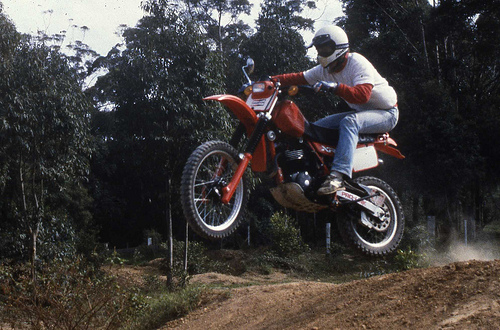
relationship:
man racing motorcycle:
[269, 20, 401, 194] [178, 54, 409, 259]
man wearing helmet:
[269, 20, 401, 194] [311, 24, 353, 70]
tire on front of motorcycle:
[178, 140, 248, 241] [265, 22, 398, 193]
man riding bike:
[269, 20, 401, 194] [186, 24, 420, 260]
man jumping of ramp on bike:
[269, 25, 400, 195] [179, 58, 407, 257]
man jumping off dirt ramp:
[269, 25, 400, 195] [156, 258, 500, 329]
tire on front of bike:
[177, 138, 251, 242] [179, 58, 407, 257]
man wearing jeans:
[269, 20, 401, 194] [295, 104, 461, 216]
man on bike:
[269, 25, 400, 195] [179, 55, 409, 260]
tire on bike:
[178, 140, 248, 241] [179, 55, 409, 260]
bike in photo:
[176, 92, 408, 247] [5, 5, 496, 327]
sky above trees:
[64, 5, 115, 48] [6, 2, 245, 291]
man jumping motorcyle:
[269, 20, 401, 194] [177, 58, 403, 262]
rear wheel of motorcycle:
[337, 174, 407, 261] [182, 73, 413, 252]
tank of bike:
[274, 103, 311, 139] [179, 58, 407, 257]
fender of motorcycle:
[245, 137, 272, 174] [182, 73, 413, 252]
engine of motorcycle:
[276, 142, 319, 193] [178, 54, 409, 259]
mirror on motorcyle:
[244, 57, 256, 72] [177, 58, 403, 262]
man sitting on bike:
[269, 25, 400, 195] [179, 58, 407, 257]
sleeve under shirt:
[269, 72, 308, 88] [302, 54, 395, 104]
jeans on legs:
[311, 103, 401, 178] [312, 106, 400, 196]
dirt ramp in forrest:
[167, 253, 499, 327] [1, 6, 498, 251]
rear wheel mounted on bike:
[337, 176, 406, 258] [172, 65, 414, 325]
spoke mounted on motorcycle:
[194, 154, 236, 226] [178, 54, 409, 259]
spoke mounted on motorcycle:
[220, 203, 230, 219] [178, 54, 409, 259]